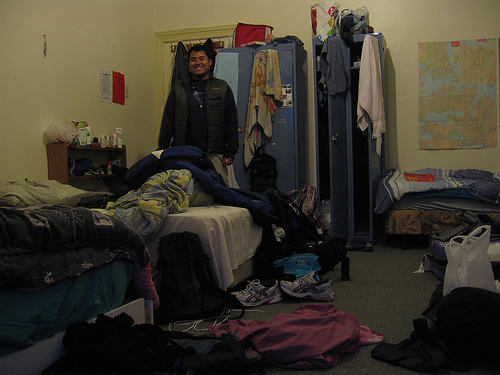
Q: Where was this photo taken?
A: In a bedroom.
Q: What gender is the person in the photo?
A: Male.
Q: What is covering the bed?
A: Clothes.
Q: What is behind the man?
A: A door.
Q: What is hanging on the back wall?
A: A map.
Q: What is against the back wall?
A: Lockers.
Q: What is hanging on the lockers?
A: Clothes.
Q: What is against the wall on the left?
A: A shelf.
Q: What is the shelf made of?
A: Wood.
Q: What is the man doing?
A: Smiling.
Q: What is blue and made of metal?
A: The blue locker.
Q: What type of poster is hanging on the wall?
A: A map.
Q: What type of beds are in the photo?
A: Twin beds.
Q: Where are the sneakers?
A: On the floor.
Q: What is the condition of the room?
A: Messy.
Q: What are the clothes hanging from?
A: Lockers.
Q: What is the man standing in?
A: A bedroom.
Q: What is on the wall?
A: A map.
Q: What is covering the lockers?
A: Clothes and towels.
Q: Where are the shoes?
A: On the floor.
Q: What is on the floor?
A: Clothes.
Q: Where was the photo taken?
A: In a messy room.